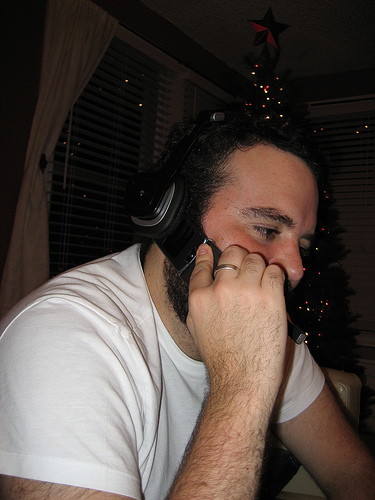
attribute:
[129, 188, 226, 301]
cellphone — black, flip, flip phone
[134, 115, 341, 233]
headphones — black, parted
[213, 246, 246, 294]
ring — wedding ring, silver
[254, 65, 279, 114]
christmas tree — decorated, lit, large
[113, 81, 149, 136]
blinds — white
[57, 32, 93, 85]
curtains — white, sheer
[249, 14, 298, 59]
star — red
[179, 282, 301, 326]
knuckle — hairy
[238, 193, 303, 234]
eyebrow — black, thick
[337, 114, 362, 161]
mini blinds — light colored